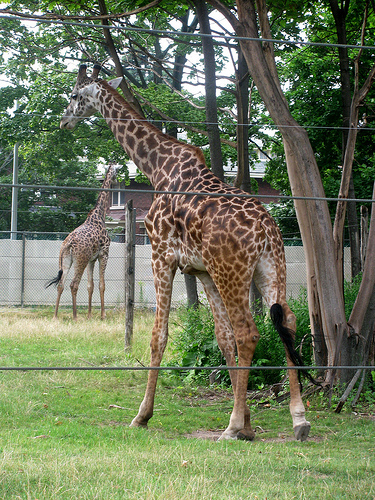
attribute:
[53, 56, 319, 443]
mammal — is spotted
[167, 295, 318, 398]
bush — green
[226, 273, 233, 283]
spot — dark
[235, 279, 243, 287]
spot — dark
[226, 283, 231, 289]
spot — dark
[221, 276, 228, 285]
spot — dark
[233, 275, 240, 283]
spot — dark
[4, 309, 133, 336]
grass — brown 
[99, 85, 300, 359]
spots — dark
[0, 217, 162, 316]
fence — metal chain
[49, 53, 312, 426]
giraffe — looking 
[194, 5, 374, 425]
tree — Large 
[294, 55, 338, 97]
leaves — green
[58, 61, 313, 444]
giraffes — fenced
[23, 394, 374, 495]
grass — brown 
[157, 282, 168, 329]
spots — dark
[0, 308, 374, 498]
grass — brown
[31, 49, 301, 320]
giraffe — spotted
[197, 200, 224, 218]
spots — dark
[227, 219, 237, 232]
spot — brown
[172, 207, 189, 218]
spot — dark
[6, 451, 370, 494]
grass — green